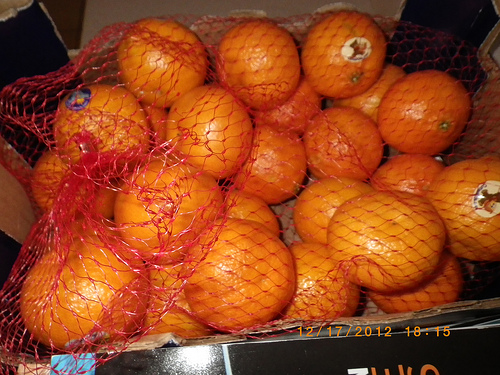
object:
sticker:
[347, 38, 369, 60]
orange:
[217, 19, 303, 112]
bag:
[4, 6, 500, 336]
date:
[296, 325, 393, 336]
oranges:
[164, 86, 251, 179]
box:
[0, 302, 500, 374]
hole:
[89, 186, 148, 223]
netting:
[0, 11, 500, 317]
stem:
[351, 75, 360, 84]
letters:
[421, 363, 436, 375]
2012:
[354, 325, 392, 338]